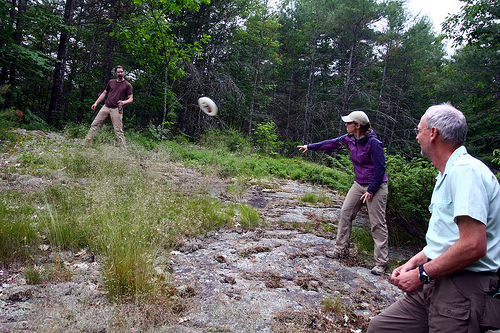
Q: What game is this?
A: Catch.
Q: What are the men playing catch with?
A: Frisbee.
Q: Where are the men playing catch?
A: Slight dirt and grass covered hill.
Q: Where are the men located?
A: Forest.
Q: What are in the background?
A: Tall green trees.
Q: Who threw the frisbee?
A: The lady in purple.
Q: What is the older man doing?
A: Watching the two people playing frisbee.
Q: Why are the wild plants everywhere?
A: Because the area is not maintained.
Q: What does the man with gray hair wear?
A: A short sleeves shirt.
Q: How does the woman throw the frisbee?
A: By extending her hand.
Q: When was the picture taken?
A: Daytime.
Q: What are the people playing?
A: Frisbee.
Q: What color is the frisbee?
A: White.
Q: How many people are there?
A: Three.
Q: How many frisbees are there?
A: One.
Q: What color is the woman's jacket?
A: Purple.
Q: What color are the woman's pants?
A: Khaki.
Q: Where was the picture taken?
A: At a park.